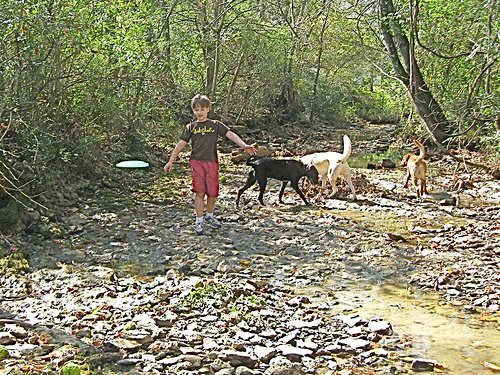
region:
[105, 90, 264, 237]
boy getting ready to catch a frisbee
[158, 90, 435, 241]
boy has three dogs with him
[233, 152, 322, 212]
one of the dogs is black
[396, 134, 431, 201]
one of the dogs is brown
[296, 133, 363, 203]
one of the dogs is a yellow lab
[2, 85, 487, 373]
our boy and dogs are in a dry creek bed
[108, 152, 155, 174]
the frisbee looks light blue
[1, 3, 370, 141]
young trees line the empty creek bed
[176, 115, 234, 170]
boy wearing a black t-shirt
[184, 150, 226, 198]
boy is wearing red shorts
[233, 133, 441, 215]
three dogs walking in a woods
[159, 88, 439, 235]
young boy with three dogs walking in woods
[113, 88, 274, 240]
young boy throwing a Frisbee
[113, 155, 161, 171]
Green Frisbee being thrown by a boy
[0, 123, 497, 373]
multitudes of rocks covering the ground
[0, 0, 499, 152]
Many trees growing in a woods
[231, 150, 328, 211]
black dog tromping in the woods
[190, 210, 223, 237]
tennis shoes of young boy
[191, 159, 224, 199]
red shorts being worn by boy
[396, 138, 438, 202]
back of brown dog running in the woods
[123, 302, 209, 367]
stones on the ground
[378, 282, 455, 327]
brown spot on the ground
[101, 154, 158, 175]
white frisbee on the ground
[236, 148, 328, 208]
black dog walking by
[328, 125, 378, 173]
wagging tail on white dog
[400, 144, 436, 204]
brown dog wagging his tail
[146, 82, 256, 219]
boy walking on the ground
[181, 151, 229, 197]
red pair of pants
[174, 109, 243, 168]
brown shirt with gold words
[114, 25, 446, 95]
forest of green trees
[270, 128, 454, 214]
dogs sniffing around in the woods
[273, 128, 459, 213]
dogs sniffing on the ground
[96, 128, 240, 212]
a freezbie thrown by a kid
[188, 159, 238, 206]
a kid wearing red shorts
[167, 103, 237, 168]
a kid wearing a brown shirt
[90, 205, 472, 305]
leaves scattered on the ground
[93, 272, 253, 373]
rocks scattered on the ground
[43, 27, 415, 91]
trees surrounding the woods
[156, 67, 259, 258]
he is walking along a creek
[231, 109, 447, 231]
there are three dogs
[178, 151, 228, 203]
his shorts are red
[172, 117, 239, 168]
his tee shirt is brown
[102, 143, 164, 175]
a white frisbee in the air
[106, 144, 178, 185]
the flying disc is midair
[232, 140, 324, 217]
this is a black dog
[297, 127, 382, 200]
this is a golden dog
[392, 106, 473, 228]
this dog is brown